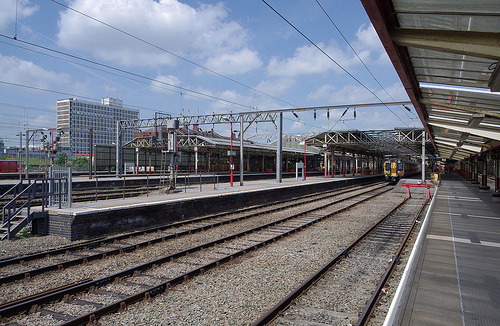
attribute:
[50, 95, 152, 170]
building — white, large, multi-storied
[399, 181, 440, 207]
bench — red, small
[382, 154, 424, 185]
train car — yellow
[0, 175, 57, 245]
steps — metal, short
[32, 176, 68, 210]
railing — dark grey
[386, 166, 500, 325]
platform — gray, cement, light grey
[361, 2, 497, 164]
station cover — hanging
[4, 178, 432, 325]
train tracks — dark brown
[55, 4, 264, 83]
clouds — white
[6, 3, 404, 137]
sky — blue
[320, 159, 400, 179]
barricade — red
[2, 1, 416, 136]
cables — black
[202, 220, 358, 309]
gravel — grey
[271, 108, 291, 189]
pole — metal, grey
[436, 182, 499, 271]
lines — white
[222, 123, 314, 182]
poles — red